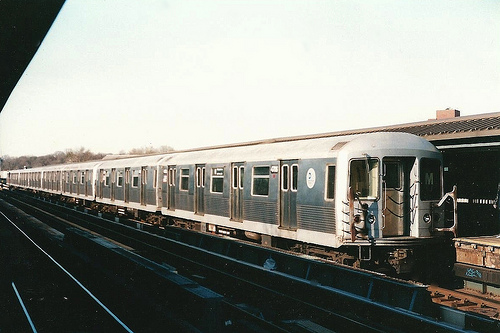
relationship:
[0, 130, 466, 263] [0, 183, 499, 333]
train parked on rails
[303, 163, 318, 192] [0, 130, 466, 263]
sign on side of train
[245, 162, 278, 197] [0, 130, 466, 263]
window on side of train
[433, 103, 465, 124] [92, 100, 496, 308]
chimney on top of building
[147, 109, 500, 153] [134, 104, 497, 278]
roof on top of train station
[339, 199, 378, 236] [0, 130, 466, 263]
chains on train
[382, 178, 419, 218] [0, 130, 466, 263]
chains on train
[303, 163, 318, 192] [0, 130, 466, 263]
sign on train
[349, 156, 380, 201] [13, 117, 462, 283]
window on front of train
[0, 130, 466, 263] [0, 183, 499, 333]
train on rails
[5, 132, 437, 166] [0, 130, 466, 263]
roof on train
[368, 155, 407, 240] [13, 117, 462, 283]
door on front of train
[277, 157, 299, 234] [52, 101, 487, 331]
door on train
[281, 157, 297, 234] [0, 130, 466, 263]
door on train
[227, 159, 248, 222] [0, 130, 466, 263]
door on train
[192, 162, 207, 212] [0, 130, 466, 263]
door on train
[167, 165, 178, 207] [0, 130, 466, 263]
door on train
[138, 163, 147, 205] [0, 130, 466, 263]
door on train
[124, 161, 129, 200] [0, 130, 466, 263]
door on train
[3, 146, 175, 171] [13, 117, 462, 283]
trees behind train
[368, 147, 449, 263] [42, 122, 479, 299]
doorway in front of train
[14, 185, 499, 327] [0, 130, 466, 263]
rails below train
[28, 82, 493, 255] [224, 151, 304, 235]
train has doors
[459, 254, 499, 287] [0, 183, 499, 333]
graffiti on rails